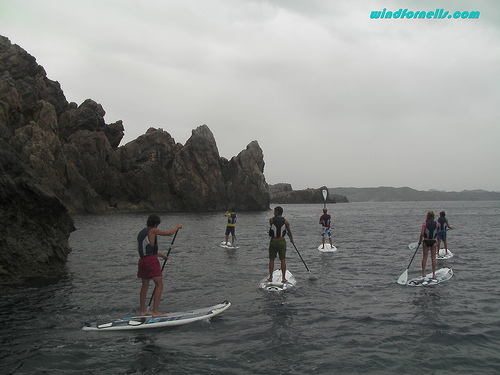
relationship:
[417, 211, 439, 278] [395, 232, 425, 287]
person holding paddle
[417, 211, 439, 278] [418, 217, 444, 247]
person wearing shirt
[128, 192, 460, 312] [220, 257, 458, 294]
people on boards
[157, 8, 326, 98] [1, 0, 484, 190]
cloud in sky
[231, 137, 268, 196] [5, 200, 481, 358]
cliff over water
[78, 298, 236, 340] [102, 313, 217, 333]
board with edge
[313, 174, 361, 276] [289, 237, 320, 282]
man with oar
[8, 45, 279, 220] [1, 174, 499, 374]
rocky terrain over water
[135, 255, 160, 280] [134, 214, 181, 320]
red shorts on man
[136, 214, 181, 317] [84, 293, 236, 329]
man on paddleboard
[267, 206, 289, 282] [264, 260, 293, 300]
man on paddleboard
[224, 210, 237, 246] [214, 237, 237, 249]
man on paddleboard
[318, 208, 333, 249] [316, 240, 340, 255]
man on paddleboard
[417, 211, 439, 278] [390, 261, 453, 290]
person on a paddleboard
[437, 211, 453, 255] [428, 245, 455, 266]
people on a paddleboard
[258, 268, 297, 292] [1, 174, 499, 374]
paddleboard on water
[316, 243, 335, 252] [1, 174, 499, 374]
paddleboard on water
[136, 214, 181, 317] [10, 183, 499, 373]
man in ocean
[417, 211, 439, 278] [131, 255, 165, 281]
person wearing pink shorts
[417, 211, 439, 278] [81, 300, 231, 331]
person on a board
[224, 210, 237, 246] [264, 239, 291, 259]
man wearing swim trunks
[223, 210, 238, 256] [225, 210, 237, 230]
man wearing yellow shirt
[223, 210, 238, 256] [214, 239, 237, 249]
man on paddleboard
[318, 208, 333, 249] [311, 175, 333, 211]
man holding h paddle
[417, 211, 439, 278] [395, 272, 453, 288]
person on a paddleboard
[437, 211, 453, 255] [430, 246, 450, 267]
people on a paddleboard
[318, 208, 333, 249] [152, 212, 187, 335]
man holding paddle